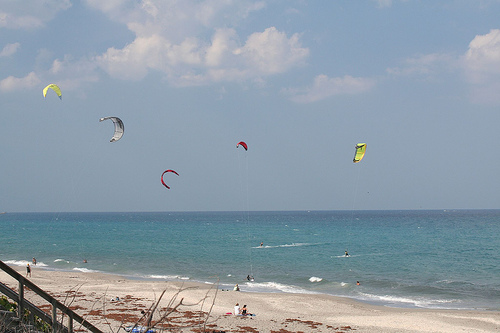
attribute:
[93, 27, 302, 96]
cloud — white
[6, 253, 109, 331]
railing — wooden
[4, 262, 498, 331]
beach — sandy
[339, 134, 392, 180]
kite — yellow, flying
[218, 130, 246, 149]
kite — flying, red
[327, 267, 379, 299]
person — swimming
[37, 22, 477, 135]
sky — white, cloudy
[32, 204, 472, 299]
waves — blue, beautiful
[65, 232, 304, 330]
waves — white, crashing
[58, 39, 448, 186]
sky — white, cloudy, blue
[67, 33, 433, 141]
sky — white, cloudy, blue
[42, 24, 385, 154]
sky — blue, white, cloudy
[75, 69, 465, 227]
sky — cloudy, blue, white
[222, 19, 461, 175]
sky — white, cloudy, blue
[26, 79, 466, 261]
sky — cloudy, white, blue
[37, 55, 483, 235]
sky — blue, white, cloudy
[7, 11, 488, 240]
sky — cloudy, blue, white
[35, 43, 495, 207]
sky — white, blue, cloudy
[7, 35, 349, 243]
sky — cloudy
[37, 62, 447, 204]
sky — cloudy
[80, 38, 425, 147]
sky — cloudy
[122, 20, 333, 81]
clouds — white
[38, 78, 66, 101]
kite — yellow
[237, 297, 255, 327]
person — standing up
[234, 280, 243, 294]
person — sitting down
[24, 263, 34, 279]
person — standing up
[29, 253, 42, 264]
person — standing up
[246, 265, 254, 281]
person — standing up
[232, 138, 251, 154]
c kite — red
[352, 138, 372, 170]
c kite — yellow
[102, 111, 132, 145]
c kite — gray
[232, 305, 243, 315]
top — white 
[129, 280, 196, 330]
branch — wood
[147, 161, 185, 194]
c-kite — yellow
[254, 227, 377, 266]
people — water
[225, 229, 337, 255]
waves — sea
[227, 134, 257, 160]
kite — red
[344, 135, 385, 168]
kite — yellow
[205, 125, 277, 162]
kite — sky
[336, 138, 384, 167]
kite — sky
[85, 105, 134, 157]
kite — white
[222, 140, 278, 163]
kite — red 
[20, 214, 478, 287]
water — body 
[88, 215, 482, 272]
water — calm